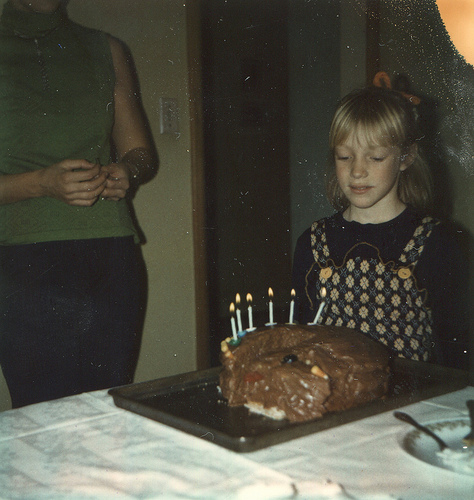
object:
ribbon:
[372, 69, 422, 106]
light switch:
[157, 93, 179, 135]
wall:
[77, 2, 209, 384]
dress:
[309, 207, 440, 362]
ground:
[396, 153, 440, 197]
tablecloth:
[0, 379, 473, 499]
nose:
[351, 149, 367, 179]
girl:
[290, 82, 473, 377]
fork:
[391, 409, 447, 453]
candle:
[228, 302, 241, 346]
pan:
[107, 356, 469, 454]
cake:
[217, 322, 395, 423]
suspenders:
[309, 215, 438, 269]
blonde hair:
[325, 86, 439, 214]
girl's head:
[326, 89, 419, 208]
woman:
[1, 0, 158, 406]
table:
[0, 341, 473, 498]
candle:
[308, 287, 330, 326]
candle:
[285, 287, 298, 325]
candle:
[263, 285, 277, 326]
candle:
[244, 292, 257, 332]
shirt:
[0, 18, 149, 248]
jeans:
[2, 232, 147, 406]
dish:
[393, 410, 473, 481]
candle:
[234, 293, 245, 336]